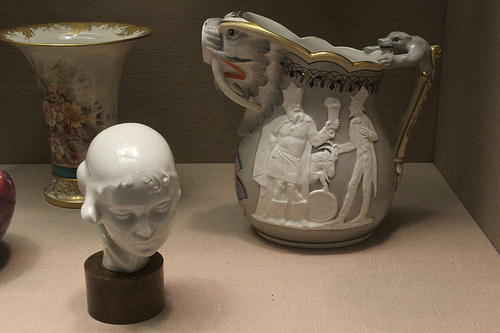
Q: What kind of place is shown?
A: It is a display.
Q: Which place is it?
A: It is a display.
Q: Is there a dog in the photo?
A: No, there are no dogs.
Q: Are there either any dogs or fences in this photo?
A: No, there are no dogs or fences.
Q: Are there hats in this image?
A: Yes, there is a hat.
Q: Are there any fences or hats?
A: Yes, there is a hat.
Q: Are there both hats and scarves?
A: No, there is a hat but no scarves.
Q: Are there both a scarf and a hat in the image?
A: No, there is a hat but no scarves.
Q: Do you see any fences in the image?
A: No, there are no fences.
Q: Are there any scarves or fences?
A: No, there are no fences or scarves.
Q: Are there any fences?
A: No, there are no fences.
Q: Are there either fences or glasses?
A: No, there are no fences or glasses.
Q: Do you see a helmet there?
A: No, there are no helmets.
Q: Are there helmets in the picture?
A: No, there are no helmets.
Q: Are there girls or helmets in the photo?
A: No, there are no helmets or girls.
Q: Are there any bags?
A: No, there are no bags.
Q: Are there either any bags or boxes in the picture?
A: No, there are no bags or boxes.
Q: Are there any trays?
A: No, there are no trays.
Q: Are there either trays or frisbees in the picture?
A: No, there are no trays or frisbees.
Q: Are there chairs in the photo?
A: No, there are no chairs.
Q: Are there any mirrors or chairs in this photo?
A: No, there are no chairs or mirrors.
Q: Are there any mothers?
A: No, there are no mothers.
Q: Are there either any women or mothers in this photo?
A: No, there are no mothers or women.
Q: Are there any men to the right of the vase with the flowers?
A: Yes, there are men to the right of the vase.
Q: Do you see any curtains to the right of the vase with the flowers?
A: No, there are men to the right of the vase.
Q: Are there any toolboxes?
A: No, there are no toolboxes.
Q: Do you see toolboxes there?
A: No, there are no toolboxes.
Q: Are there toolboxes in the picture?
A: No, there are no toolboxes.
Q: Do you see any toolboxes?
A: No, there are no toolboxes.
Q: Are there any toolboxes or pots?
A: No, there are no toolboxes or pots.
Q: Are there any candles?
A: No, there are no candles.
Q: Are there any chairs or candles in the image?
A: No, there are no candles or chairs.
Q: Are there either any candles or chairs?
A: No, there are no candles or chairs.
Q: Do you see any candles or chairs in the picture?
A: No, there are no candles or chairs.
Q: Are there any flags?
A: No, there are no flags.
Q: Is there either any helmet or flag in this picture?
A: No, there are no flags or helmets.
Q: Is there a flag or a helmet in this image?
A: No, there are no flags or helmets.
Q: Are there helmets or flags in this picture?
A: No, there are no flags or helmets.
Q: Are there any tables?
A: Yes, there is a table.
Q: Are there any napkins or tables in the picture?
A: Yes, there is a table.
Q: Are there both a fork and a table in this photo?
A: No, there is a table but no forks.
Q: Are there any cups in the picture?
A: No, there are no cups.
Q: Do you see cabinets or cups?
A: No, there are no cups or cabinets.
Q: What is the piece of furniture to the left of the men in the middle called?
A: The piece of furniture is a table.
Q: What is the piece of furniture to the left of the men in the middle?
A: The piece of furniture is a table.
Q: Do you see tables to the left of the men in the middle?
A: Yes, there is a table to the left of the men.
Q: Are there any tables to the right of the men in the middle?
A: No, the table is to the left of the men.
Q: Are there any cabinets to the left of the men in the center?
A: No, there is a table to the left of the men.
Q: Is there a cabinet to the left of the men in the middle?
A: No, there is a table to the left of the men.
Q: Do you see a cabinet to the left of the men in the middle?
A: No, there is a table to the left of the men.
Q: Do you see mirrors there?
A: No, there are no mirrors.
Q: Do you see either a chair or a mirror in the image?
A: No, there are no mirrors or chairs.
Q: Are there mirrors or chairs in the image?
A: No, there are no mirrors or chairs.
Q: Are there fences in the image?
A: No, there are no fences.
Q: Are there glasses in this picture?
A: No, there are no glasses.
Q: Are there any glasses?
A: No, there are no glasses.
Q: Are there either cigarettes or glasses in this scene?
A: No, there are no glasses or cigarettes.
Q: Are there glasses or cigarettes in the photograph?
A: No, there are no glasses or cigarettes.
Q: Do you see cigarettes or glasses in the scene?
A: No, there are no glasses or cigarettes.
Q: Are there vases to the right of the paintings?
A: Yes, there is a vase to the right of the paintings.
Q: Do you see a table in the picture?
A: Yes, there is a table.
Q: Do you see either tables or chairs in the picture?
A: Yes, there is a table.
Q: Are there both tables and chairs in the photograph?
A: No, there is a table but no chairs.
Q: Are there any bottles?
A: No, there are no bottles.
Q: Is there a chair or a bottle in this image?
A: No, there are no bottles or chairs.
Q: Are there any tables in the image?
A: Yes, there is a table.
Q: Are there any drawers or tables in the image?
A: Yes, there is a table.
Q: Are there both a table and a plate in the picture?
A: No, there is a table but no plates.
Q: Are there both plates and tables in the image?
A: No, there is a table but no plates.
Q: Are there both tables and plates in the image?
A: No, there is a table but no plates.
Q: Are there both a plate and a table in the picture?
A: No, there is a table but no plates.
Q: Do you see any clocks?
A: No, there are no clocks.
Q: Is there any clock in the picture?
A: No, there are no clocks.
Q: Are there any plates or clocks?
A: No, there are no clocks or plates.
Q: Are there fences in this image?
A: No, there are no fences.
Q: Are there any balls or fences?
A: No, there are no fences or balls.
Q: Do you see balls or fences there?
A: No, there are no fences or balls.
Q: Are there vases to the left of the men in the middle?
A: Yes, there is a vase to the left of the men.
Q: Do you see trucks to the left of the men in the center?
A: No, there is a vase to the left of the men.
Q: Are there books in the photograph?
A: No, there are no books.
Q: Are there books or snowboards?
A: No, there are no books or snowboards.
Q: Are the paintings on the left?
A: Yes, the paintings are on the left of the image.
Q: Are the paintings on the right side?
A: No, the paintings are on the left of the image.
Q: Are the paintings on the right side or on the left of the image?
A: The paintings are on the left of the image.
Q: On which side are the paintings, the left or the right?
A: The paintings are on the left of the image.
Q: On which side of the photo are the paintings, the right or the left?
A: The paintings are on the left of the image.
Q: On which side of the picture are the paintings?
A: The paintings are on the left of the image.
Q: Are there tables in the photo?
A: Yes, there is a table.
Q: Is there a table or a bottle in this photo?
A: Yes, there is a table.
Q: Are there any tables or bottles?
A: Yes, there is a table.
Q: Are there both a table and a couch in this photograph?
A: No, there is a table but no couches.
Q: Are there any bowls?
A: No, there are no bowls.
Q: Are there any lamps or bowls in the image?
A: No, there are no bowls or lamps.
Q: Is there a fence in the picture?
A: No, there are no fences.